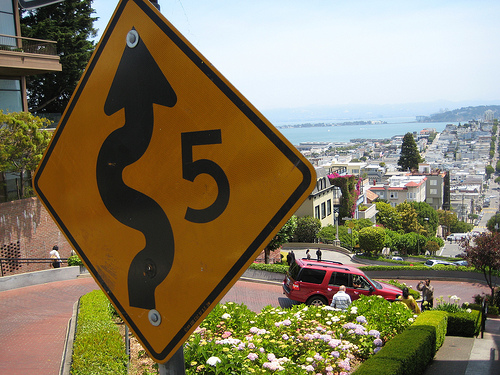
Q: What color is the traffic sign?
A: Yellow.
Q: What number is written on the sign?
A: 5.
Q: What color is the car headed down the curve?
A: Red.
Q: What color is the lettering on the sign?
A: Black.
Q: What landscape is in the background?
A: Ocean.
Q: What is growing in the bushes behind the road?
A: Flowers.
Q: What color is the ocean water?
A: Blue.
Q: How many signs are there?
A: One.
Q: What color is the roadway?
A: Red.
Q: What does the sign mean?
A: Winding road.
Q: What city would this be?
A: San Francisco.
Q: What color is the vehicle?
A: Red.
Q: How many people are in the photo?
A: 8.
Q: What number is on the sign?
A: 5.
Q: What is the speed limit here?
A: 5.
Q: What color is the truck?
A: Red.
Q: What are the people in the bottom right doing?
A: Taking a picture.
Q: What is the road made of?
A: Brick.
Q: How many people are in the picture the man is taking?
A: 2.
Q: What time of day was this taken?
A: Afternoon.